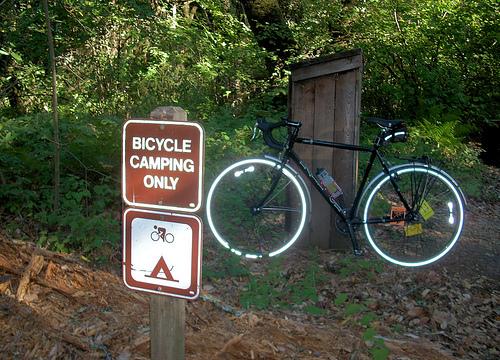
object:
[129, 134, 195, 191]
letters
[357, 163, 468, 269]
tire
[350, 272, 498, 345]
dead leaves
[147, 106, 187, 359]
wooden post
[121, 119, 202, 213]
signs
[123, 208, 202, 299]
sign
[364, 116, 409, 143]
seat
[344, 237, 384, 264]
peddle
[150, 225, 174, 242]
bike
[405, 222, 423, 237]
card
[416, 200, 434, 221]
card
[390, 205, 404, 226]
card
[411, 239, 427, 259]
spoke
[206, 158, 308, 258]
spokes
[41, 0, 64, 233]
tree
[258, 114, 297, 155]
green trees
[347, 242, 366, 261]
pedal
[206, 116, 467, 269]
bike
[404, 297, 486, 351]
leaves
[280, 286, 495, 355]
floor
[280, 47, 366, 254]
barn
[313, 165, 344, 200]
bottle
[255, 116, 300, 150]
handle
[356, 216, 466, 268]
part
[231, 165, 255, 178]
reflector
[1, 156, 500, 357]
ground